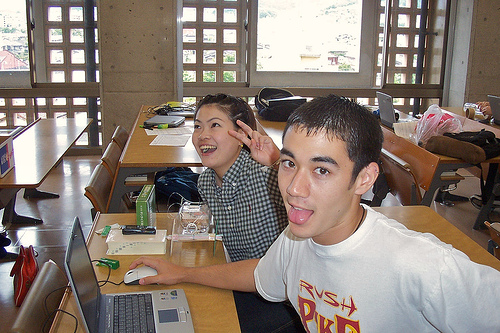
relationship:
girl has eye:
[191, 91, 296, 331] [194, 122, 203, 131]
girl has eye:
[191, 91, 296, 331] [207, 122, 222, 131]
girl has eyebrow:
[191, 91, 296, 331] [192, 118, 203, 125]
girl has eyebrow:
[191, 91, 296, 331] [204, 115, 225, 123]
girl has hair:
[191, 91, 296, 331] [194, 92, 257, 155]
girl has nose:
[191, 91, 296, 331] [197, 127, 212, 142]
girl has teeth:
[191, 91, 296, 331] [198, 144, 216, 150]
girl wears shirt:
[191, 91, 296, 331] [195, 149, 287, 267]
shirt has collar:
[195, 149, 287, 267] [198, 150, 249, 195]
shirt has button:
[195, 149, 287, 267] [225, 201, 233, 211]